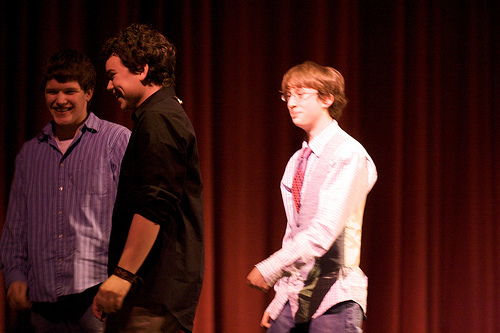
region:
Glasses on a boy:
[276, 85, 341, 99]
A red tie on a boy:
[291, 147, 311, 227]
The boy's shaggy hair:
[284, 60, 346, 115]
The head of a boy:
[281, 63, 349, 128]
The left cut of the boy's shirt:
[256, 254, 289, 284]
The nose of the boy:
[286, 96, 299, 108]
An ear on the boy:
[321, 91, 335, 110]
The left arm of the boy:
[278, 146, 370, 279]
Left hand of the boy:
[241, 268, 271, 295]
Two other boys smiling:
[3, 25, 212, 329]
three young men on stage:
[28, 24, 418, 234]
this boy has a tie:
[262, 44, 399, 252]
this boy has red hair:
[261, 18, 392, 183]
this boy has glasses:
[248, 49, 448, 259]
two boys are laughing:
[33, 20, 238, 253]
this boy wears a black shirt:
[106, 21, 211, 178]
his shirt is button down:
[28, 54, 111, 229]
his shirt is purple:
[24, 22, 138, 291]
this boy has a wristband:
[76, 18, 221, 328]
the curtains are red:
[27, 16, 486, 299]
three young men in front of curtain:
[18, 15, 385, 326]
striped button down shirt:
[8, 115, 126, 302]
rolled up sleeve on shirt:
[133, 133, 187, 235]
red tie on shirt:
[286, 143, 312, 211]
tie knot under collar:
[297, 121, 343, 160]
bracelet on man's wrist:
[110, 263, 139, 290]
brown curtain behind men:
[18, 38, 494, 323]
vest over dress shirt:
[285, 135, 357, 279]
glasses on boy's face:
[277, 86, 309, 108]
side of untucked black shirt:
[111, 93, 201, 323]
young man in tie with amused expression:
[265, 65, 374, 332]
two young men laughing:
[13, 23, 188, 258]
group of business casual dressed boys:
[15, 25, 442, 332]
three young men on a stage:
[0, 12, 407, 330]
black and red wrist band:
[108, 262, 136, 286]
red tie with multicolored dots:
[290, 150, 312, 218]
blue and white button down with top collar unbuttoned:
[7, 118, 117, 300]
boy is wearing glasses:
[277, 86, 329, 102]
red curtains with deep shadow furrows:
[383, 35, 488, 331]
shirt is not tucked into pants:
[272, 260, 364, 330]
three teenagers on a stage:
[4, 20, 391, 325]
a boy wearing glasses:
[254, 57, 353, 329]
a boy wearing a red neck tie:
[253, 42, 379, 322]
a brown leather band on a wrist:
[113, 262, 137, 282]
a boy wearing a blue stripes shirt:
[9, 43, 104, 321]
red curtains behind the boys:
[390, 16, 491, 331]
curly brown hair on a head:
[119, 32, 160, 59]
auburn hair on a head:
[301, 63, 336, 87]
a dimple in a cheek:
[116, 82, 133, 93]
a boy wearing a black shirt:
[103, 19, 209, 331]